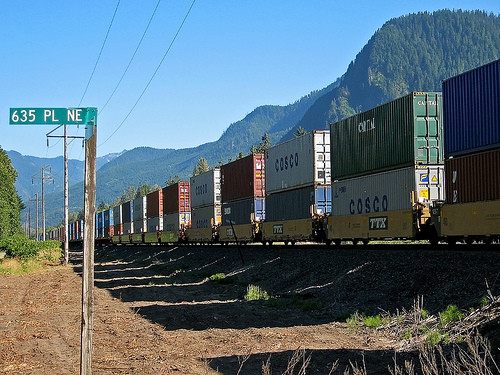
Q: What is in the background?
A: Mountains.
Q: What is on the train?
A: Freight.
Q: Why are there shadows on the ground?
A: The shadows are from the train.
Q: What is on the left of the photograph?
A: A tree.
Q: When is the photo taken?
A: Daytime.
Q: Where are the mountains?
A: The mountains are in the background.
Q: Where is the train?
A: In the countryside.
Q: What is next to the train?
A: Power Lines.